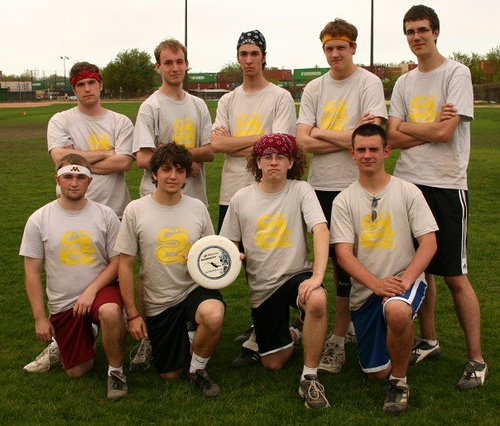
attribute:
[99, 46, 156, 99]
tree — green, large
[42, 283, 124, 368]
shorts — red 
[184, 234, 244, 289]
frisbee — white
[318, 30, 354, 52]
yellow sweatband — yellow 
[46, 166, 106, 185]
headband — white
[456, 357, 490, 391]
shoe — gray , white 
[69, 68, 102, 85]
sweat band — red 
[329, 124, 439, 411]
man — young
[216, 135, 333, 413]
man — young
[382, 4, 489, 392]
man — young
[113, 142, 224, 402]
man — young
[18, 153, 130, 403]
man — young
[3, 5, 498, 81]
sky — white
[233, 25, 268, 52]
bandanna — white, black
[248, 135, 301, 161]
bandana — red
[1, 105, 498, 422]
large field — green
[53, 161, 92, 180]
sweat band — white 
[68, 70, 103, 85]
bandana — red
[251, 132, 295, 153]
bandana — red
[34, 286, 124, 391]
shorts — burgundy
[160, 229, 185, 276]
snake — yellow 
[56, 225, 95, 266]
logo — yellow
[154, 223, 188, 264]
logo — yellow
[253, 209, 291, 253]
logo — yellow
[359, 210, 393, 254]
logo — yellow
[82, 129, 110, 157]
logo — yellow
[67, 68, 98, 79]
headband — red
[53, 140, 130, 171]
arms — folded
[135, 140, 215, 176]
arms — folded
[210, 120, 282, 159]
arms — folded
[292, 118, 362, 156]
arms — folded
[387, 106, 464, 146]
arms — folded